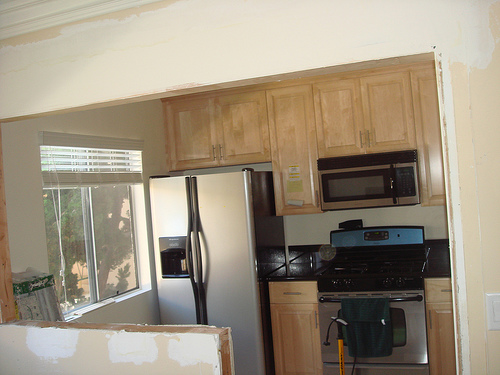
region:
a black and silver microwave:
[275, 141, 440, 232]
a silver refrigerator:
[143, 159, 267, 371]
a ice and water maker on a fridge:
[148, 229, 208, 301]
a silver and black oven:
[314, 235, 434, 371]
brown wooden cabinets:
[173, 92, 466, 204]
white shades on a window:
[20, 120, 186, 198]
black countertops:
[273, 230, 498, 299]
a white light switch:
[476, 281, 498, 335]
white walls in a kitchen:
[4, 107, 157, 234]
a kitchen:
[78, 114, 475, 365]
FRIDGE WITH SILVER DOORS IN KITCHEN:
[150, 120, 272, 367]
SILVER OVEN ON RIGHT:
[301, 289, 417, 367]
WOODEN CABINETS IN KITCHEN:
[169, 93, 499, 185]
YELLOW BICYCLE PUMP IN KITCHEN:
[322, 320, 352, 371]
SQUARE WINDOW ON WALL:
[31, 136, 159, 291]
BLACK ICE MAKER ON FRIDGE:
[161, 232, 187, 286]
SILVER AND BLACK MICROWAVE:
[314, 133, 433, 227]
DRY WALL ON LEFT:
[22, 303, 244, 372]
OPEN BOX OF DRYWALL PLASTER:
[13, 257, 67, 318]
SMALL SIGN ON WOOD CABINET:
[275, 167, 314, 215]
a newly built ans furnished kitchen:
[0, 0, 495, 366]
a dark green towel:
[336, 297, 393, 358]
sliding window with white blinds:
[37, 130, 154, 321]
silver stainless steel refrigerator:
[147, 167, 267, 372]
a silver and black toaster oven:
[318, 150, 418, 212]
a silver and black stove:
[316, 224, 428, 370]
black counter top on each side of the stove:
[266, 237, 456, 280]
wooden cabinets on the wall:
[164, 61, 449, 216]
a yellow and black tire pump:
[323, 313, 357, 373]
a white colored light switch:
[482, 292, 499, 330]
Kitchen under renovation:
[5, 12, 486, 349]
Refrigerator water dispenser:
[148, 237, 196, 286]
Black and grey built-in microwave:
[313, 155, 431, 211]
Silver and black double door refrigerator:
[139, 175, 276, 373]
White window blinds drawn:
[36, 136, 147, 190]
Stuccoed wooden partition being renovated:
[3, 315, 235, 373]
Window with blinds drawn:
[26, 129, 163, 315]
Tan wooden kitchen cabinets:
[153, 62, 440, 149]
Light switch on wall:
[471, 286, 498, 329]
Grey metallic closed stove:
[316, 218, 432, 371]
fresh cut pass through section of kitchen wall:
[16, 321, 239, 373]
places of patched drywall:
[13, 320, 225, 372]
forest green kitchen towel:
[331, 305, 397, 354]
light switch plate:
[475, 288, 499, 333]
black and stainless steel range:
[318, 228, 425, 374]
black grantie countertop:
[265, 245, 325, 290]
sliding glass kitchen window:
[41, 145, 153, 314]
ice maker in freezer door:
[154, 225, 191, 286]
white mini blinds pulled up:
[38, 142, 146, 192]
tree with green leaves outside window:
[44, 192, 145, 307]